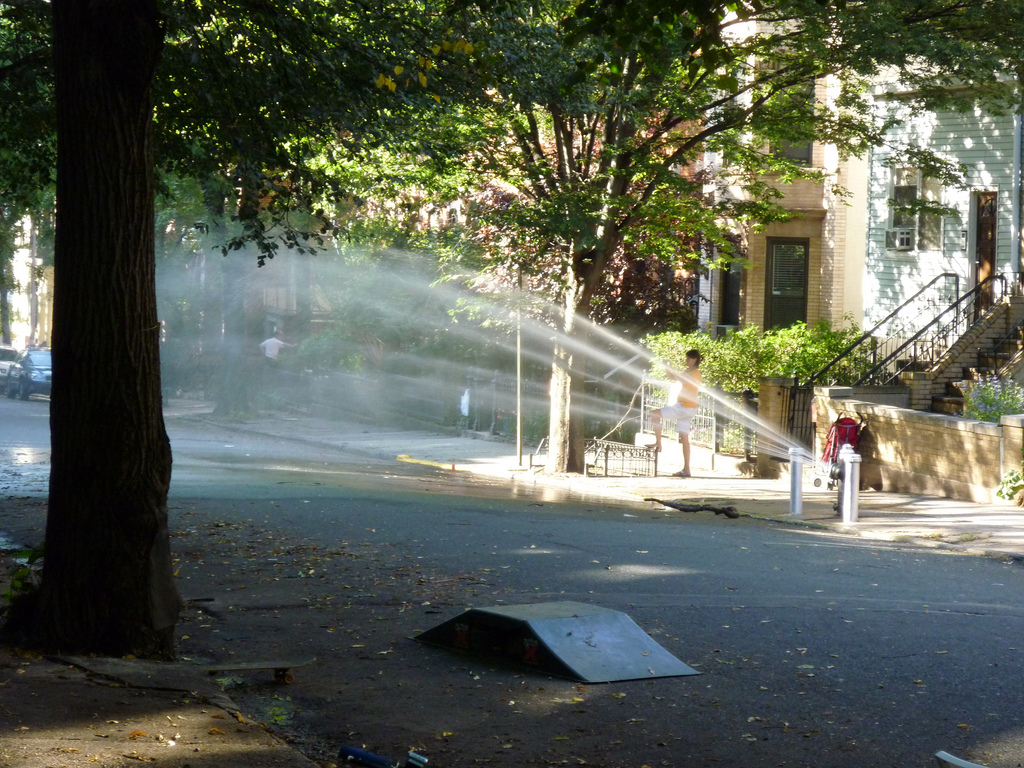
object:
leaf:
[748, 707, 761, 716]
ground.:
[2, 419, 1020, 760]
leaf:
[796, 659, 816, 673]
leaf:
[796, 642, 812, 656]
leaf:
[824, 658, 838, 675]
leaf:
[507, 696, 515, 705]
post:
[840, 453, 867, 527]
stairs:
[777, 269, 1012, 456]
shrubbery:
[736, 332, 771, 393]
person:
[659, 346, 707, 482]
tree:
[2, 0, 197, 665]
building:
[692, 0, 861, 484]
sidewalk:
[0, 538, 329, 766]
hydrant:
[837, 438, 865, 522]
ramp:
[406, 595, 705, 688]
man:
[255, 326, 295, 364]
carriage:
[826, 414, 869, 492]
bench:
[581, 428, 671, 485]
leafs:
[234, 572, 248, 593]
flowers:
[970, 375, 1023, 416]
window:
[888, 164, 920, 246]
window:
[719, 237, 741, 332]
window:
[714, 247, 742, 327]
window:
[778, 61, 802, 156]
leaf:
[792, 656, 812, 673]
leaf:
[796, 639, 816, 659]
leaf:
[821, 651, 845, 673]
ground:
[170, 487, 1002, 747]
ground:
[169, 526, 1006, 765]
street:
[20, 351, 1001, 747]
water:
[330, 340, 413, 412]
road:
[68, 365, 1001, 763]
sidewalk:
[165, 345, 994, 605]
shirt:
[249, 338, 277, 362]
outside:
[36, 61, 1003, 762]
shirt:
[654, 354, 717, 415]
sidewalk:
[194, 334, 1013, 590]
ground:
[39, 427, 939, 763]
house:
[467, 15, 1021, 473]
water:
[151, 219, 871, 559]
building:
[792, 48, 1022, 492]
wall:
[814, 406, 992, 504]